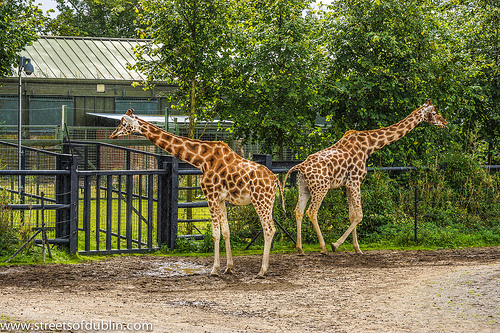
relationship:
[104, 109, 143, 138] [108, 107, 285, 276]
head of giraffe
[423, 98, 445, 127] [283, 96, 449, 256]
head of giraffe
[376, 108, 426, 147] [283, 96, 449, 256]
neck of giraffe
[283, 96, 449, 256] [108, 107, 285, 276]
giraffe opposite ro giraffe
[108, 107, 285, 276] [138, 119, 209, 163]
giraffe has neck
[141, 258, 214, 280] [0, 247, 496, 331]
mud on ground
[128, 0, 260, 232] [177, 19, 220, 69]
tree has leaves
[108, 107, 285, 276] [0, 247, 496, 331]
giraffe on ground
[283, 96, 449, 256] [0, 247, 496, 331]
giraffe walking on ground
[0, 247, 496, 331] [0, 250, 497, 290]
ground covered with mud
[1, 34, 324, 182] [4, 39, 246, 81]
building with roof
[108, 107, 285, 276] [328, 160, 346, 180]
giraffe with spots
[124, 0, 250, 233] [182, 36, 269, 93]
tree with leaves